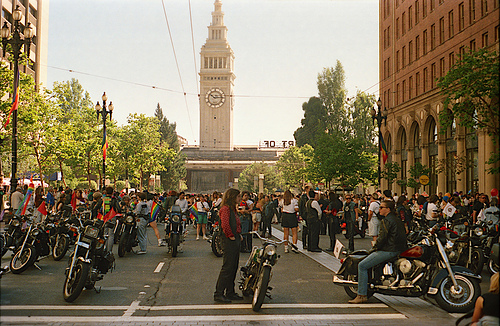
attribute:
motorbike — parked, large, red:
[336, 193, 475, 299]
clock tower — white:
[195, 13, 240, 144]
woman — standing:
[218, 204, 244, 242]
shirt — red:
[220, 209, 238, 238]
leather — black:
[380, 217, 399, 252]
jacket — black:
[385, 218, 390, 219]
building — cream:
[189, 150, 267, 188]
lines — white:
[128, 284, 220, 326]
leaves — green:
[476, 49, 492, 61]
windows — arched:
[384, 112, 458, 143]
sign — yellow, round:
[413, 166, 427, 189]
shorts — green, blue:
[195, 192, 212, 240]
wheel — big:
[436, 270, 488, 313]